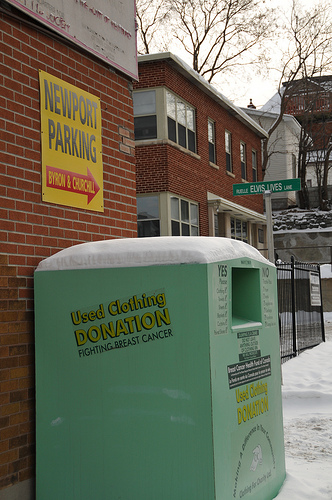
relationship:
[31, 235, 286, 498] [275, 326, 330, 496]
box on street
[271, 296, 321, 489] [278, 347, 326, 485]
ground covered in snow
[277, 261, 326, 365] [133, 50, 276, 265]
fence next to building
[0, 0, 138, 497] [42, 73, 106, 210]
brick building with sign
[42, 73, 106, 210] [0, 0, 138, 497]
sign on brick building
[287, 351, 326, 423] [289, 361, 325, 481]
snow on ground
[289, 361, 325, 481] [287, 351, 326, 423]
ground with snow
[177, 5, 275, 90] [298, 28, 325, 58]
trees with no leaves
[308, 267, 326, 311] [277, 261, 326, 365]
sign with fence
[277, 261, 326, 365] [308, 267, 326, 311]
fence with sign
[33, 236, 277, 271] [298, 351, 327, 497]
snow in area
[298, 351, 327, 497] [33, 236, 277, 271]
area with snow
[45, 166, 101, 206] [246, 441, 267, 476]
arrow for clothing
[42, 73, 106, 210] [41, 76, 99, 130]
sign with writing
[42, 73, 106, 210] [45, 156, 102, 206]
sign with arrow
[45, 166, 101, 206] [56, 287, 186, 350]
arrow with letters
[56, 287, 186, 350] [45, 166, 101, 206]
letters on arrow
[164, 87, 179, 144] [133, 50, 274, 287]
window on building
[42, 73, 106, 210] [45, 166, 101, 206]
sign with arrow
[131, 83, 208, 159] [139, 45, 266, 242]
windows with building